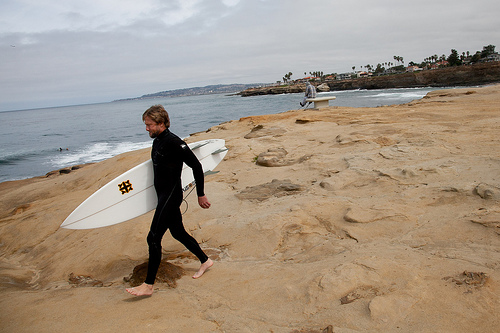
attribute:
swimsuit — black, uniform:
[144, 127, 214, 286]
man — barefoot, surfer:
[124, 104, 228, 298]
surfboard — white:
[58, 137, 229, 232]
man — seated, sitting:
[299, 80, 318, 108]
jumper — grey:
[303, 80, 317, 99]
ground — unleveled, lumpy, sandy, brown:
[1, 82, 498, 331]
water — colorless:
[0, 85, 476, 184]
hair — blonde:
[141, 103, 171, 127]